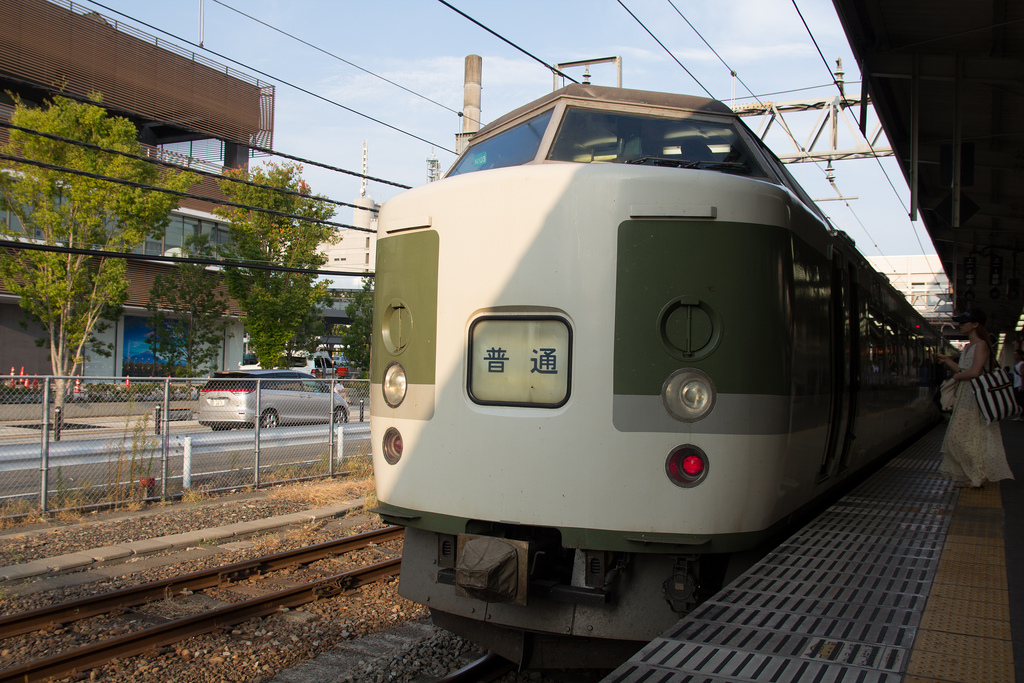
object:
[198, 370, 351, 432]
van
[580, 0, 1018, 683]
station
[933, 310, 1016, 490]
woman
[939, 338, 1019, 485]
dress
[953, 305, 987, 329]
baseball cap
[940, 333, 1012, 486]
dress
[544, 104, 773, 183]
window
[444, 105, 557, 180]
window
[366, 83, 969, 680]
train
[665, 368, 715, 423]
light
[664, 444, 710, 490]
light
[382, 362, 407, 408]
light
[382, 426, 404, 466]
light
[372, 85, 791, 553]
front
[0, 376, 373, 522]
fence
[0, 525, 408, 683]
train track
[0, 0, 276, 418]
building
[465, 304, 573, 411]
letters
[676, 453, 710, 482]
light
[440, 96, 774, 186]
windows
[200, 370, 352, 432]
car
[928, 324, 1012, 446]
woman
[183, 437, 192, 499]
pole